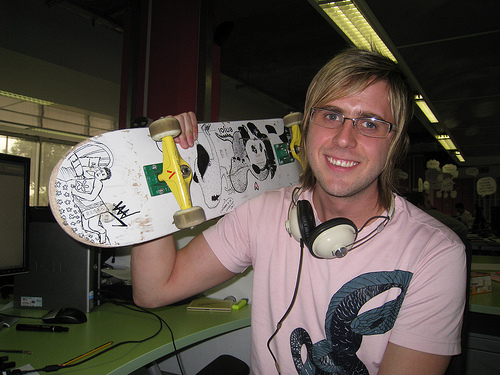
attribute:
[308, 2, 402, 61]
lights — florescent, fluorescent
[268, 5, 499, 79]
ceiling — part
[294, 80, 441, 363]
man — smiling, blonde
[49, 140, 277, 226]
skateboard — white, bottom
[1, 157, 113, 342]
computer — equipment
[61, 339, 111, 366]
pencil — yellow, sharpened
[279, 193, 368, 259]
headphones — white, large, black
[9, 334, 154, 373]
cables — electronic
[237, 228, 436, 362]
shirt — pink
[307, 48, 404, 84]
hair — blonde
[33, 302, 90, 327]
mouse — black, silver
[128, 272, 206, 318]
elbow — caucasian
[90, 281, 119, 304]
case — dell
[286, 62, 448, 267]
skateboarder — smiling